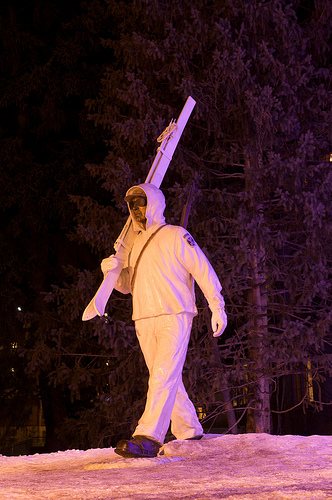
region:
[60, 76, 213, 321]
A set of wooden skiis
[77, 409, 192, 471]
Black snow boots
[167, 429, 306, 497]
Snow covered ground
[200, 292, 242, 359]
White hand gloves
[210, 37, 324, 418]
Tall green pine tree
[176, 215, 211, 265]
A patch on the suit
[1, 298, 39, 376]
Lights in the background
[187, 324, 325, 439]
Building in the background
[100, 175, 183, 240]
Ball cap and sunglasses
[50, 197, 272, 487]
Man walking through the woods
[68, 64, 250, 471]
skier walking on snow at night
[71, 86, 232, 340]
man carrying long skis over shoulder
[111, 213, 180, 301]
leather strap across body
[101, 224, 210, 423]
outfit of shiny white material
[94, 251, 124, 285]
hand over edge of skis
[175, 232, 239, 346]
arm to side with curved hand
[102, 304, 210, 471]
leading with left foot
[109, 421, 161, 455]
wide and high toe box on shoe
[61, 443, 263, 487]
gravelly surface of snow under shoe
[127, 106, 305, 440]
trees behind skier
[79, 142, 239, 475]
the man looks very determined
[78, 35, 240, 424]
he is carrying his skis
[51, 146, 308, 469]
the entire photo appears to be in purple tint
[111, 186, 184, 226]
the man is wearing goggles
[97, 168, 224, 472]
the man is dressed in white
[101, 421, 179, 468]
the man has on black boots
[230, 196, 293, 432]
the evergreen trees look purple in the light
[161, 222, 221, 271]
the man has a patch on his sleeve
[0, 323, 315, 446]
it appears there is a lodge or house in the background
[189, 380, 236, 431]
one can see the lights through the trees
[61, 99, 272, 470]
a man carrying a pair of skis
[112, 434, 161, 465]
thick black snow boots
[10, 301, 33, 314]
a street light in the distance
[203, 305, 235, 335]
a white glove covering a hand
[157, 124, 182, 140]
a metal tie on the skir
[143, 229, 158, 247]
a leather strap across a chest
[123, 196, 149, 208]
snow goggles covering eyes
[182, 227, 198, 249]
a patch on a sleeve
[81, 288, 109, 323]
the curved end of a pair of skis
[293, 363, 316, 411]
a light shining through a window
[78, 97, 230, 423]
statue of man with skis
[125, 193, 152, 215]
glasses on statue face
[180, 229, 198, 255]
emblem on statue arm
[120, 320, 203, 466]
walking legs on statue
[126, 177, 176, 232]
hood over statue head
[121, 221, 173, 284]
strap around statue body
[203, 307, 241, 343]
white gloves on hand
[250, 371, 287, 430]
trunk of evergreen tree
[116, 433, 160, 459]
dark boot on statue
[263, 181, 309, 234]
branches on evergreen tree